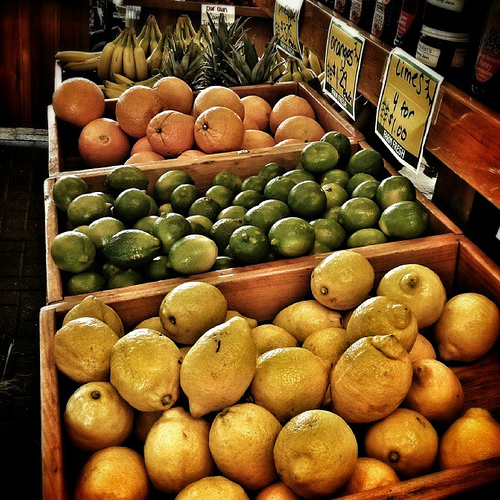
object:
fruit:
[53, 12, 500, 497]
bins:
[33, 234, 499, 497]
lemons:
[327, 329, 413, 420]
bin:
[34, 233, 499, 500]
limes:
[49, 229, 96, 273]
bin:
[15, 135, 464, 298]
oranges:
[192, 105, 245, 153]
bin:
[35, 79, 362, 177]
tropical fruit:
[58, 17, 321, 84]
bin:
[41, 34, 330, 114]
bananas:
[150, 15, 194, 73]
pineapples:
[209, 14, 289, 87]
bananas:
[265, 38, 326, 90]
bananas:
[100, 70, 163, 101]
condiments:
[415, 20, 473, 85]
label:
[411, 39, 443, 66]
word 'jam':
[422, 51, 431, 63]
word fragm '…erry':
[415, 50, 423, 56]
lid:
[418, 19, 472, 42]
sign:
[202, 3, 236, 31]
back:
[1, 0, 274, 130]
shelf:
[259, 3, 499, 218]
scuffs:
[428, 89, 500, 205]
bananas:
[98, 23, 151, 81]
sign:
[369, 43, 445, 173]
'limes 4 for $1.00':
[379, 58, 424, 144]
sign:
[318, 30, 367, 106]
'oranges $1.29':
[329, 34, 352, 88]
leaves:
[229, 30, 252, 82]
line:
[212, 341, 224, 357]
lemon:
[177, 310, 262, 419]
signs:
[272, 0, 306, 63]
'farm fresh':
[0, 4, 499, 499]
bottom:
[458, 362, 497, 406]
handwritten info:
[324, 28, 365, 106]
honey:
[473, 38, 500, 110]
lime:
[95, 227, 168, 267]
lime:
[285, 176, 330, 218]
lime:
[263, 215, 324, 257]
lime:
[153, 212, 191, 247]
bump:
[157, 209, 170, 219]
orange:
[77, 118, 130, 165]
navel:
[95, 131, 106, 145]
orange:
[142, 109, 196, 155]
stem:
[151, 123, 168, 135]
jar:
[420, 1, 476, 33]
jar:
[369, 0, 398, 41]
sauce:
[371, 1, 384, 40]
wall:
[0, 0, 89, 140]